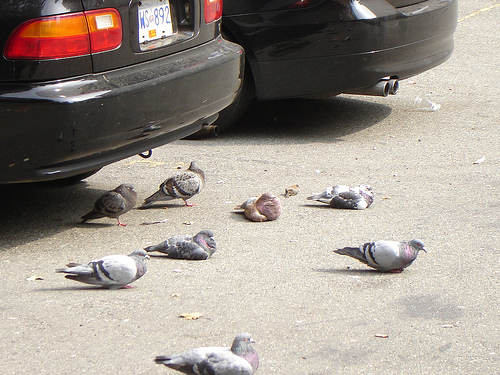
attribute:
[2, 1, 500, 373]
road — paved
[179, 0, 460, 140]
car — black, on the right, parked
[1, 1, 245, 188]
car — black, on the left, parked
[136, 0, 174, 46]
licence plate — blue, white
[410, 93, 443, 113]
cups — discarded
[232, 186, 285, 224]
bird — lying down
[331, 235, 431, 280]
pigeon — sitting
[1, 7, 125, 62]
light — red, yellow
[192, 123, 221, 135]
exhaust pipe — small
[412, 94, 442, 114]
cup — plastic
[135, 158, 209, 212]
pigeon — standing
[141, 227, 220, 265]
pigeon — lying down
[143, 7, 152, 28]
letter — blue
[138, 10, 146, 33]
letter — blue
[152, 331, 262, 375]
pigeon — gray, white